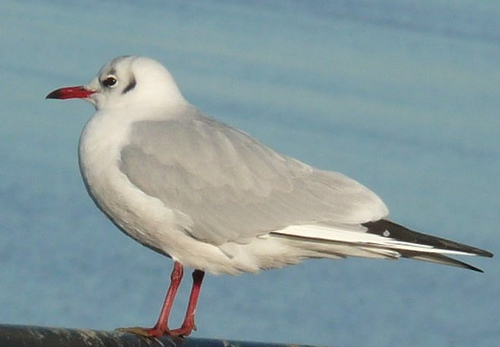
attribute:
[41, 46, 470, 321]
bird — small, white, perched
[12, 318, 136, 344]
rail — black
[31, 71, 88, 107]
beak — orange, red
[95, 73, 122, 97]
eye — black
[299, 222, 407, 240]
feather — long, grey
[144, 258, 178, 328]
leg — red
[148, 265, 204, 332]
legs — red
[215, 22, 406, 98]
sky — cloudy, blue